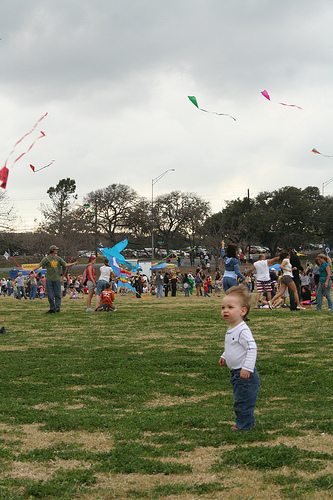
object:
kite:
[259, 88, 283, 107]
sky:
[173, 40, 211, 67]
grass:
[138, 361, 187, 383]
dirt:
[157, 396, 177, 404]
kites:
[185, 92, 239, 122]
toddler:
[205, 280, 258, 416]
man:
[31, 243, 67, 315]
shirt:
[97, 292, 111, 304]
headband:
[88, 257, 93, 260]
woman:
[83, 254, 97, 315]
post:
[149, 184, 155, 209]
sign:
[1, 175, 11, 183]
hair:
[230, 286, 237, 297]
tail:
[8, 105, 48, 150]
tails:
[286, 101, 304, 112]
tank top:
[83, 267, 91, 283]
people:
[145, 247, 237, 316]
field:
[0, 350, 97, 427]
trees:
[153, 216, 206, 243]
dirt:
[20, 424, 319, 495]